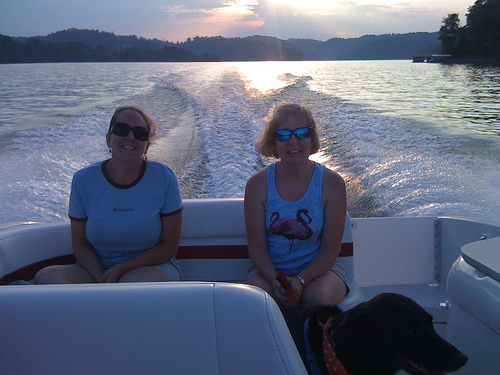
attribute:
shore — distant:
[0, 51, 225, 64]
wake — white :
[372, 114, 499, 215]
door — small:
[352, 214, 437, 286]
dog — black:
[277, 289, 469, 374]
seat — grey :
[36, 270, 299, 363]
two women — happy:
[242, 102, 349, 307]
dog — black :
[281, 278, 466, 373]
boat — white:
[1, 195, 496, 370]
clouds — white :
[3, 3, 469, 40]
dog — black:
[273, 294, 465, 373]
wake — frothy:
[157, 82, 242, 162]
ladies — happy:
[58, 91, 358, 318]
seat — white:
[6, 272, 311, 370]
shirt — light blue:
[258, 154, 329, 283]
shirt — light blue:
[64, 150, 184, 268]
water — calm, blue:
[0, 53, 498, 230]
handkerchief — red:
[322, 303, 345, 364]